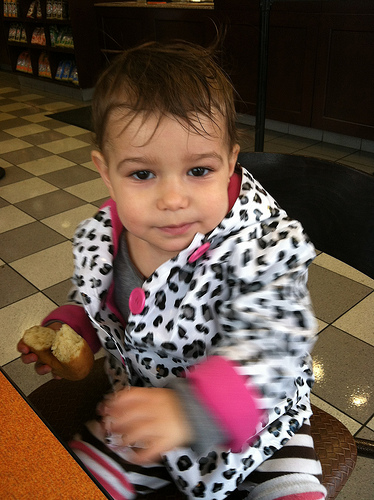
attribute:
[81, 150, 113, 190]
ear — toddler's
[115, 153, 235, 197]
eyes — brown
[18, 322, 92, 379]
donut — regular, plain, brown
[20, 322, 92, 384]
donut — partially eaten, half eaten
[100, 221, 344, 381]
jacket — leopard print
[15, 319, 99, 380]
donut — half eaten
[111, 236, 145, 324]
shirt — grey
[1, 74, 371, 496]
floor — grey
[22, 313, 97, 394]
donut — half eaten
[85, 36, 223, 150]
hair — messy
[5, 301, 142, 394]
donut — partially eaten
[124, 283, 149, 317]
button — pink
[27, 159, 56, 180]
tile — white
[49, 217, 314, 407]
jacket — animal print, pink